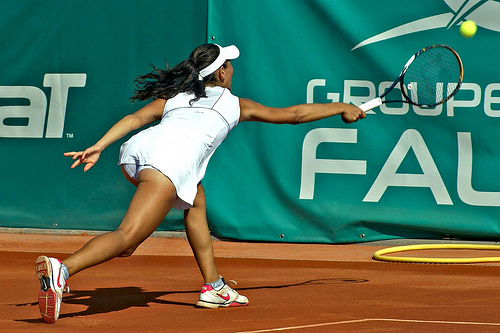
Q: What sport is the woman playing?
A: Tennis.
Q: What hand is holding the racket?
A: Right hand.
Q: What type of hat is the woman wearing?
A: Visor.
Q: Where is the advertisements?
A: On the wall.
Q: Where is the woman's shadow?
A: On the court.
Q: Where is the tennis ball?
A: In the air.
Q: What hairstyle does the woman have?
A: Ponytail.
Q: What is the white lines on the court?
A: Boundary lines.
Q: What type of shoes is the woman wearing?
A: Tennis shoes.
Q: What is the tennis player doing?
A: Hitting ball.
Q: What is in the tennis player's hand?
A: Tennis racket.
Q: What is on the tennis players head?
A: White visor.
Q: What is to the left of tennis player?
A: Shadow.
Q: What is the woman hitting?
A: Tennis ball.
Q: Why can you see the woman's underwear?
A: The woman is bent forward.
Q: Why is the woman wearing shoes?
A: To protect the feet.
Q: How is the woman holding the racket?
A: In the right hand.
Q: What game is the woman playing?
A: Tennis.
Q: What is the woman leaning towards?
A: The ball.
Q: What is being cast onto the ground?
A: The woman's shadow.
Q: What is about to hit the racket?
A: A tennis ball.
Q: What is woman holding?
A: Racket.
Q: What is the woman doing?
A: Playing tennis.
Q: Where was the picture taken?
A: On a tennis court.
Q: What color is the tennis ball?
A: Yellow.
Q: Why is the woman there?
A: To play tennis.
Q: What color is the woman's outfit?
A: White.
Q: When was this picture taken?
A: In the daytime.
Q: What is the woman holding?
A: A tennis racket.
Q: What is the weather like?
A: Sunny.